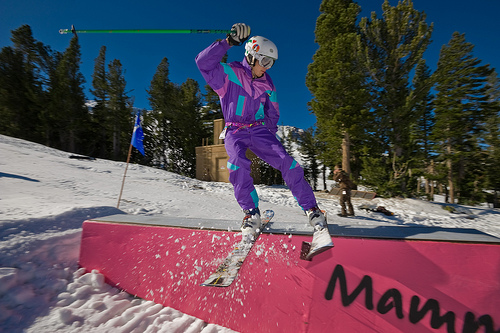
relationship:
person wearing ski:
[197, 20, 327, 236] [309, 227, 334, 259]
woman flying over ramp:
[191, 22, 325, 234] [77, 210, 498, 326]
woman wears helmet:
[193, 35, 324, 234] [233, 29, 283, 63]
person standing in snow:
[332, 164, 357, 217] [364, 203, 414, 243]